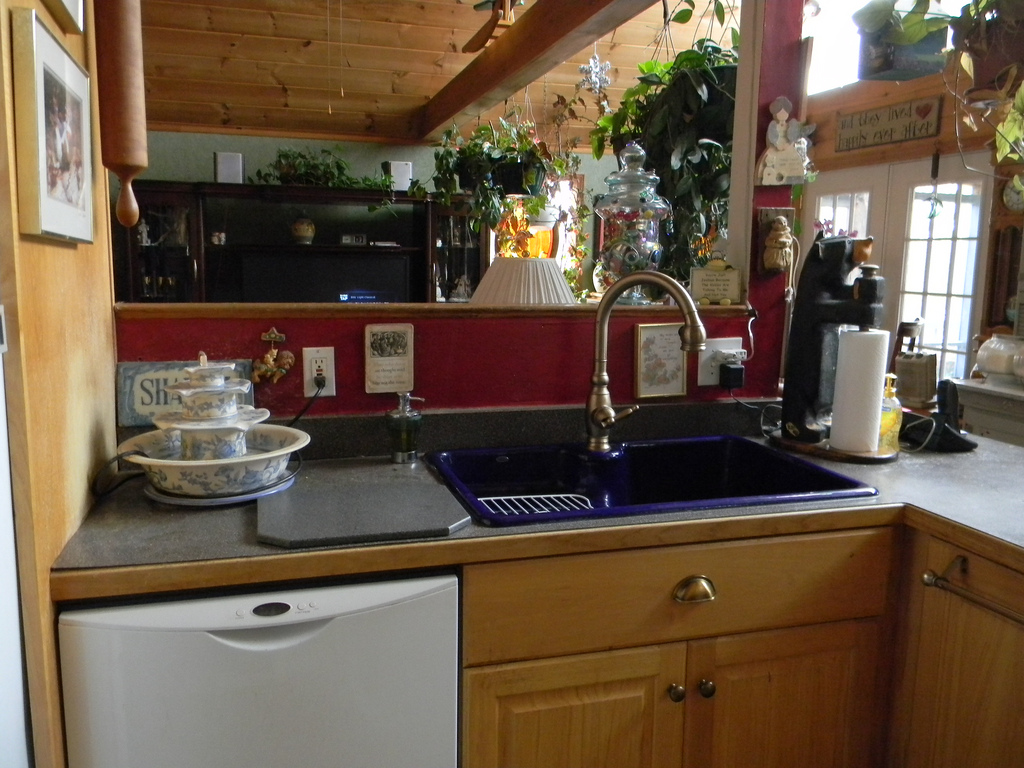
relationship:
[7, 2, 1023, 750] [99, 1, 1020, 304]
kitchen next to family room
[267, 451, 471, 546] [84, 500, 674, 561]
chopping board on counter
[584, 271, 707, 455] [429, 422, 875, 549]
faucet on sink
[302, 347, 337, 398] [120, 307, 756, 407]
electrical outlet on wall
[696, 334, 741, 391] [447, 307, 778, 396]
power outlet on wall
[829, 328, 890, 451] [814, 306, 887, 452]
paper towel standing holder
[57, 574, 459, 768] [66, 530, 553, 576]
dish washer under counter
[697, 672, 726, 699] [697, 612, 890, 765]
knob on cabinet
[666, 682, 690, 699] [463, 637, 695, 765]
knob on cabinet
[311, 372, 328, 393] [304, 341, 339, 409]
plug in a socket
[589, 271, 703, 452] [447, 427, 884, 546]
faucet of sink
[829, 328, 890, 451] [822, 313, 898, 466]
paper towel of paper towels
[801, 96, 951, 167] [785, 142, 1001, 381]
sign hanging over a doorway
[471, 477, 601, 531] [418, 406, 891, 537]
rack in a sink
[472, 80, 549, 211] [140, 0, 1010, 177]
plant hanging from ceiling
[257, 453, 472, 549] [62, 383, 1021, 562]
chopping board on a counter top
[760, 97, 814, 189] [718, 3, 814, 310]
decorative piece hanging on post